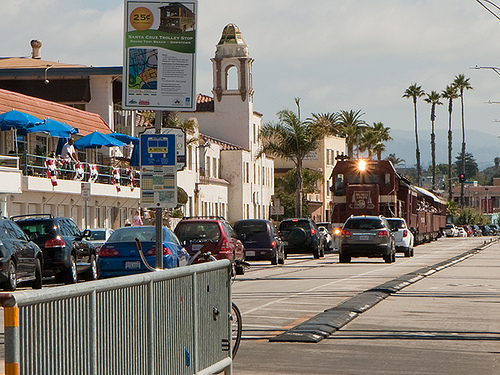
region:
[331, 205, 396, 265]
The back of a vehicle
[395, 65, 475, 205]
Four tall palm trees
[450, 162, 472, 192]
Traffic light lit up red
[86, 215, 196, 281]
A blue colored car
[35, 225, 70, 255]
A red rear light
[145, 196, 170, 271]
Gray post holding up signs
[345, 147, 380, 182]
A light is brightly lit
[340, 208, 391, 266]
car on a street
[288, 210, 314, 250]
car on a street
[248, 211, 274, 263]
car on a street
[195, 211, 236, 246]
car on a street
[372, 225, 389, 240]
light on a car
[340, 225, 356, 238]
light on a car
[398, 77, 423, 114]
tree near a building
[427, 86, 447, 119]
tree near a building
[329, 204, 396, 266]
This is a car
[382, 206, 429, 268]
This is a car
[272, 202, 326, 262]
This is a car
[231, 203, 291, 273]
This is a car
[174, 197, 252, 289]
This is a car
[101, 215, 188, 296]
This is a car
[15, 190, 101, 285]
This is a car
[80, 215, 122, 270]
This is a car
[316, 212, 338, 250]
This is a car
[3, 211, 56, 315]
This is a car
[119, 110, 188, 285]
Bus stop sign on the pole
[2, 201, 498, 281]
Cars going in one direction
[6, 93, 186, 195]
People standing on the first floor balcony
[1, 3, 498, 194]
Cloudy sky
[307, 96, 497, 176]
Mountains in the background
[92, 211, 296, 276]
Red car between black and blue car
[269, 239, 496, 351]
Slightly raised road divider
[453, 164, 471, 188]
Red traffic signal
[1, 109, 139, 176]
Blue umbrellas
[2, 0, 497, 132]
cloud cover in sky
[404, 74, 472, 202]
leaves on tall palm trees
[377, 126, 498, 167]
hazy mountains on horizon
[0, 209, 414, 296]
back of cars on road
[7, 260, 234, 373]
metal rails of gate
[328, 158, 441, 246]
front of commuter trolley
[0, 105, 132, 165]
blue fabric of umbrellas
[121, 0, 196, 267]
two signs on pole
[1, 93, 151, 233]
balcony on second story of building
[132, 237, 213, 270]
handlebars of parked bike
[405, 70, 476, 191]
four tall palm trees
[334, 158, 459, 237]
a red and white passenger train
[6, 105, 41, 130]
a blue outdoor umbrella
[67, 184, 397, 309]
the cars are moving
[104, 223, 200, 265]
the car is blue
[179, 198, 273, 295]
the other car is red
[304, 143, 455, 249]
the train is moving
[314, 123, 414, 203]
the train lights are yellow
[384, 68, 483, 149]
these are palm trees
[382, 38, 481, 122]
the palm trees are tall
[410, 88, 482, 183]
the palm trees are thin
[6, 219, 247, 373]
tram car waiting area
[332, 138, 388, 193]
the reflection of the sun on the tram car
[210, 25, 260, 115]
the dome on top of the building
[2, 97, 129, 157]
blue umbrellas to protect from the sun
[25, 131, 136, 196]
a man standing on the balcony